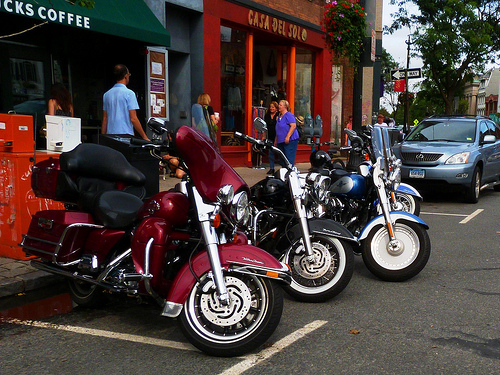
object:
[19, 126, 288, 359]
motorcycles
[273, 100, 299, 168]
people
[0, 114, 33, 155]
machines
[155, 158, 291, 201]
sidewalk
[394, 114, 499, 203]
car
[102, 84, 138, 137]
shirt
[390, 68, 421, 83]
sign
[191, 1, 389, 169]
building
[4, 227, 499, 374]
ground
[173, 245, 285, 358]
wheel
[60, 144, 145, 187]
seat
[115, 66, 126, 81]
hair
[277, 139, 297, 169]
pants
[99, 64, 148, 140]
man